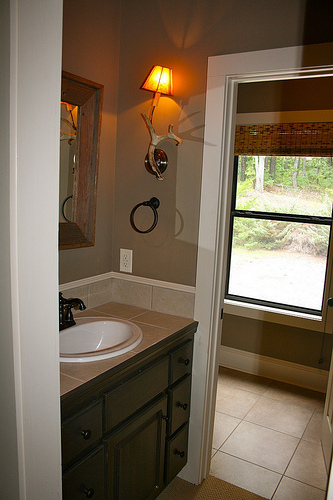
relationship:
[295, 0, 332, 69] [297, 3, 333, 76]
part of a ventilation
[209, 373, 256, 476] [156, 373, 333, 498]
part of a floor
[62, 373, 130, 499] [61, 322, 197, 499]
part of a cupboard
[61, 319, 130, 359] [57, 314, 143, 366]
part of a sink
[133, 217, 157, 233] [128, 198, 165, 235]
part of a handle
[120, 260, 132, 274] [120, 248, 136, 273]
part of a switch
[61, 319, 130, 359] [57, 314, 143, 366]
part of sink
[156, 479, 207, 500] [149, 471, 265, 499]
part of a carpet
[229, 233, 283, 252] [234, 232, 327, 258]
part of a boundary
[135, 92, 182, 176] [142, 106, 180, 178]
fixture partially made antler